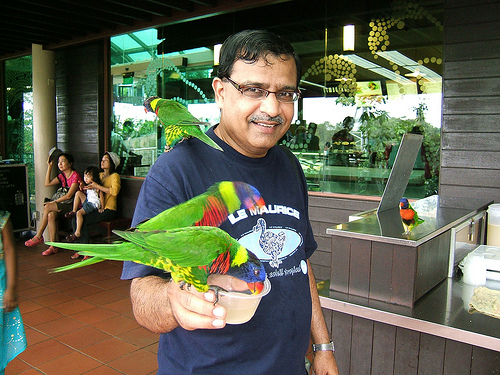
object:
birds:
[162, 175, 278, 291]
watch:
[313, 341, 336, 354]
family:
[24, 146, 130, 261]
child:
[65, 166, 105, 242]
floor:
[0, 242, 158, 375]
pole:
[32, 43, 58, 242]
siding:
[436, 34, 500, 217]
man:
[120, 30, 339, 375]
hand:
[165, 278, 275, 330]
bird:
[143, 96, 224, 153]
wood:
[327, 229, 449, 305]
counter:
[326, 194, 445, 247]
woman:
[70, 152, 120, 262]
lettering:
[268, 204, 300, 220]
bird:
[398, 198, 425, 236]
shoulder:
[147, 138, 209, 189]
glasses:
[225, 76, 298, 103]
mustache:
[249, 113, 284, 124]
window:
[107, 0, 435, 201]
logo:
[323, 86, 349, 93]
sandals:
[41, 246, 58, 255]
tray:
[470, 286, 500, 320]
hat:
[107, 150, 121, 169]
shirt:
[99, 172, 122, 211]